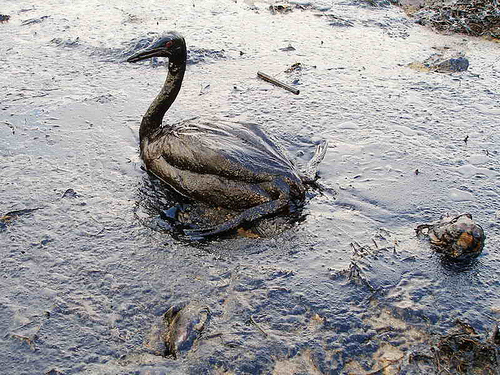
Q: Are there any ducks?
A: Yes, there is a duck.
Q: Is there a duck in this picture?
A: Yes, there is a duck.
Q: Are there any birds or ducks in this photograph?
A: Yes, there is a duck.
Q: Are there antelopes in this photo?
A: No, there are no antelopes.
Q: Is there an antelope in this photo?
A: No, there are no antelopes.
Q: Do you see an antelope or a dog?
A: No, there are no antelopes or dogs.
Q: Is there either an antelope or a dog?
A: No, there are no antelopes or dogs.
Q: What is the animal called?
A: The animal is a duck.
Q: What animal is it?
A: The animal is a duck.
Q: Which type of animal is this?
A: This is a duck.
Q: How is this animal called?
A: This is a duck.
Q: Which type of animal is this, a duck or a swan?
A: This is a duck.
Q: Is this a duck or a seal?
A: This is a duck.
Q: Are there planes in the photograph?
A: No, there are no planes.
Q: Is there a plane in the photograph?
A: No, there are no airplanes.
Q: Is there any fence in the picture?
A: No, there are no fences.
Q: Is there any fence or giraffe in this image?
A: No, there are no fences or giraffes.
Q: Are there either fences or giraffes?
A: No, there are no fences or giraffes.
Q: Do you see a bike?
A: No, there are no bikes.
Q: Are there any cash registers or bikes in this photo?
A: No, there are no bikes or cash registers.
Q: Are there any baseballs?
A: No, there are no baseballs.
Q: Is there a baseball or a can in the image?
A: No, there are no baseballs or cans.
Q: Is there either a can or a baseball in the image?
A: No, there are no baseballs or cans.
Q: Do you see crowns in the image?
A: No, there are no crowns.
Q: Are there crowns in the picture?
A: No, there are no crowns.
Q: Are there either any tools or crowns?
A: No, there are no crowns or tools.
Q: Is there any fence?
A: No, there are no fences.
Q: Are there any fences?
A: No, there are no fences.